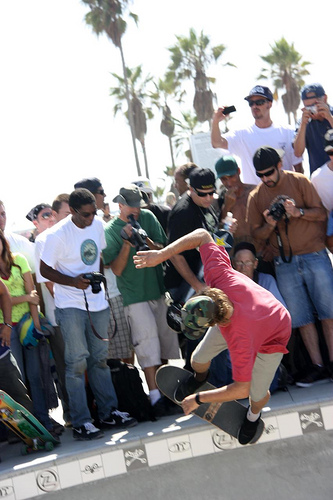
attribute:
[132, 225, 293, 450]
man — skateboarding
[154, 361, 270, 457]
board — black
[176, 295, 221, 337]
helmet — for safety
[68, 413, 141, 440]
shoes — nike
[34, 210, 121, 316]
shirt — white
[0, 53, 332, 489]
they — wearing sunglasses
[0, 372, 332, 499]
tiles — white, rim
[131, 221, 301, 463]
he — wearing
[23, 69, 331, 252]
hats — different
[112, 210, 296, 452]
skateboarder — performing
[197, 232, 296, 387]
shirt — red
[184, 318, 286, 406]
shorts — khaki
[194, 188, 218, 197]
sunglasses — black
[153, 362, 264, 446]
skateboard — black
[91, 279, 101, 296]
extended lens — black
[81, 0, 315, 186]
trees — palm, tall, slender, tropical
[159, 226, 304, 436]
skateboarder — camouflage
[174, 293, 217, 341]
camouflage hat — green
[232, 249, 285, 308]
man — elderly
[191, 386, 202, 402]
band — black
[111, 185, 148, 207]
hat — folded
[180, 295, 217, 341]
hat — army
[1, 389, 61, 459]
skateboard — green, yellow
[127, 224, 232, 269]
arm — lifted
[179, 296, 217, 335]
hat — camouflage